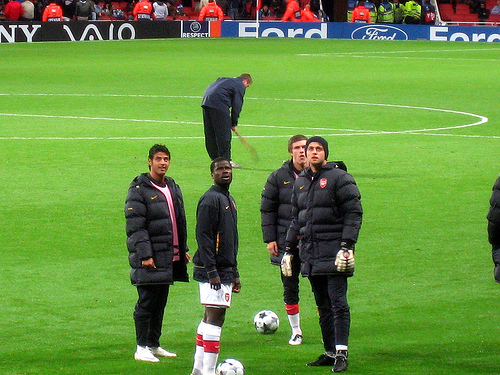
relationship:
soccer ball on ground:
[255, 304, 277, 340] [7, 49, 497, 374]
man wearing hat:
[279, 135, 364, 374] [299, 132, 331, 160]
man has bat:
[197, 69, 254, 163] [229, 130, 261, 161]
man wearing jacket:
[279, 135, 364, 374] [280, 160, 370, 281]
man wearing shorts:
[184, 156, 241, 374] [192, 270, 230, 307]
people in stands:
[0, 0, 438, 25] [0, 0, 437, 27]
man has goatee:
[184, 156, 241, 374] [218, 172, 233, 189]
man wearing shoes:
[284, 135, 365, 373] [301, 332, 361, 372]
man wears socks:
[189, 139, 296, 343] [179, 331, 261, 369]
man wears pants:
[284, 135, 365, 373] [309, 278, 351, 353]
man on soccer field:
[126, 135, 184, 362] [4, 41, 496, 373]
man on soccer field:
[184, 156, 241, 374] [4, 41, 496, 373]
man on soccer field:
[265, 130, 330, 349] [4, 41, 496, 373]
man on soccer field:
[284, 135, 365, 373] [4, 41, 496, 373]